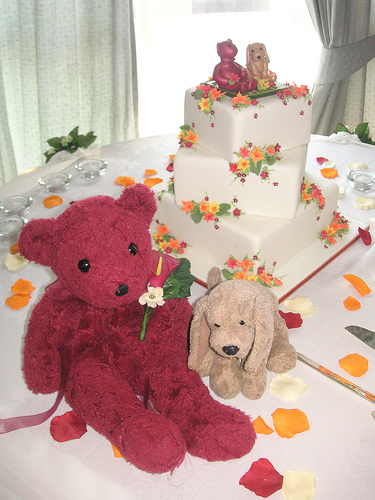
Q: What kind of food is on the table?
A: A cake.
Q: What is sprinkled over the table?
A: Flower petals.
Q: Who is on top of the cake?
A: The bear and dog.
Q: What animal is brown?
A: The dog.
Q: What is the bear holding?
A: A flower.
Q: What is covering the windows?
A: Curtains.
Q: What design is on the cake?
A: Floral.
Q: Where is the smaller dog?
A: On top of the cake.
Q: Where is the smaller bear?
A: On top of the cake.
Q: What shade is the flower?
A: White.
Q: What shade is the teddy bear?
A: Red.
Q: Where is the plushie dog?
A: Next to red teddy bear.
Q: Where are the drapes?
A: On the window.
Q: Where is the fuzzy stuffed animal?
A: On the table.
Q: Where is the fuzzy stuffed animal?
A: On the table.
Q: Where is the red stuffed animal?
A: Next to brown stuffed animal.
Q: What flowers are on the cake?
A: Orange and red.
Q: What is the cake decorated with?
A: Flowers and a bear and a puppy.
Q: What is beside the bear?
A: The dog.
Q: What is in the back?
A: Curtains.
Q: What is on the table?
A: A table cloth.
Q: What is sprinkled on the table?
A: Flower petals.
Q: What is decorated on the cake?
A: Flowers.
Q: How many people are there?
A: None.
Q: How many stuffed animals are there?
A: Two.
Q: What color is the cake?
A: White.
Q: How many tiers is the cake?
A: Three.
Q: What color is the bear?
A: Red.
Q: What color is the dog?
A: Tan.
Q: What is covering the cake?
A: Flowers.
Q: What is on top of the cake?
A: Animals.